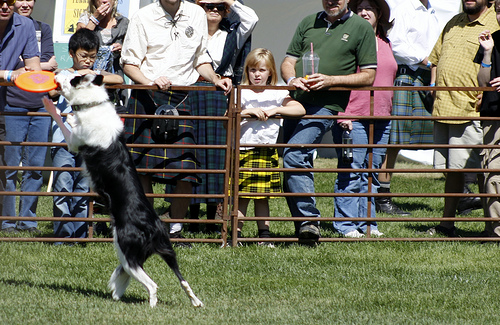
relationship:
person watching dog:
[233, 48, 303, 233] [49, 70, 203, 322]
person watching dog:
[283, 1, 398, 240] [49, 70, 203, 322]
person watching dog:
[0, 5, 256, 75] [49, 70, 203, 322]